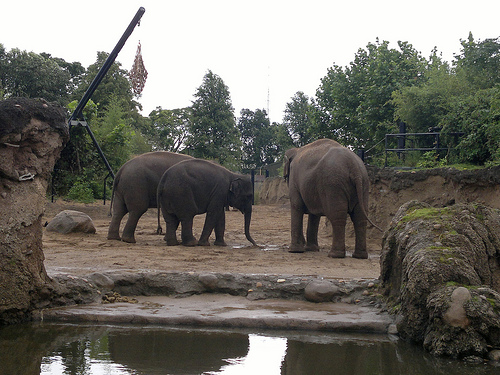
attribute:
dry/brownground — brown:
[48, 203, 379, 277]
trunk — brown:
[238, 205, 257, 245]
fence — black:
[378, 126, 471, 166]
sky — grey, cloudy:
[205, 24, 330, 88]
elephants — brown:
[108, 143, 376, 268]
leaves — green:
[333, 46, 429, 146]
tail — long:
[332, 149, 390, 257]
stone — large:
[375, 196, 498, 372]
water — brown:
[0, 320, 499, 372]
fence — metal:
[386, 132, 451, 158]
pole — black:
[55, 6, 164, 127]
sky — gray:
[4, 4, 499, 80]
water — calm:
[1, 331, 398, 374]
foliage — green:
[3, 56, 491, 190]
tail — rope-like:
[347, 172, 381, 236]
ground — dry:
[65, 217, 445, 316]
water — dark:
[32, 321, 382, 372]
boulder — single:
[42, 207, 98, 247]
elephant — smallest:
[154, 158, 259, 247]